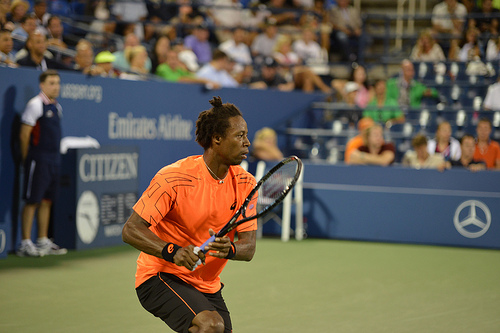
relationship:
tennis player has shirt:
[113, 93, 303, 332] [132, 146, 258, 299]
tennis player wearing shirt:
[113, 93, 303, 332] [132, 146, 258, 299]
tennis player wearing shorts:
[113, 93, 303, 332] [137, 269, 233, 332]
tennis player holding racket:
[113, 93, 303, 332] [199, 147, 304, 270]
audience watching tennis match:
[0, 4, 499, 168] [3, 97, 499, 331]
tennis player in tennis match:
[113, 93, 303, 332] [3, 97, 499, 331]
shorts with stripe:
[23, 157, 64, 202] [25, 162, 39, 197]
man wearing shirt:
[13, 71, 70, 253] [25, 96, 66, 155]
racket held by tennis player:
[199, 147, 304, 270] [113, 93, 303, 332]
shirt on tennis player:
[132, 146, 258, 299] [113, 93, 303, 332]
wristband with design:
[159, 242, 183, 260] [163, 241, 176, 255]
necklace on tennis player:
[205, 160, 228, 186] [113, 93, 303, 332]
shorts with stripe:
[137, 269, 233, 332] [156, 273, 197, 319]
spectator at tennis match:
[352, 120, 393, 168] [3, 97, 499, 331]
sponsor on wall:
[451, 197, 492, 242] [250, 157, 499, 249]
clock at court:
[99, 192, 140, 237] [4, 220, 499, 332]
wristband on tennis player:
[159, 242, 183, 260] [113, 93, 303, 332]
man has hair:
[13, 71, 70, 253] [35, 70, 60, 84]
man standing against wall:
[13, 71, 70, 253] [2, 66, 330, 275]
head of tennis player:
[198, 99, 250, 168] [113, 93, 303, 332]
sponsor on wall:
[78, 148, 141, 184] [2, 66, 330, 275]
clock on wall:
[99, 192, 140, 237] [2, 66, 330, 275]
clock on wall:
[73, 189, 104, 248] [2, 66, 330, 275]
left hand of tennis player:
[206, 226, 232, 260] [113, 93, 303, 332]